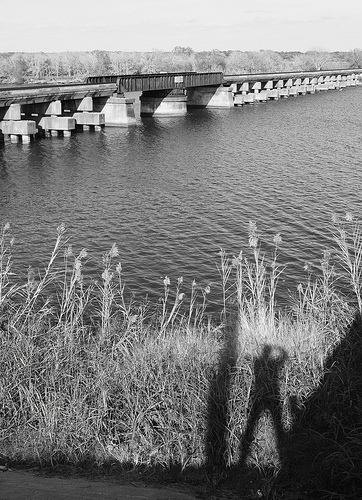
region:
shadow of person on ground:
[240, 332, 304, 458]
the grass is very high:
[4, 220, 348, 463]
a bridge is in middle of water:
[1, 45, 354, 124]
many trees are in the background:
[2, 43, 336, 108]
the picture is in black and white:
[0, 3, 353, 494]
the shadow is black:
[215, 333, 311, 491]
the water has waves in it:
[48, 141, 352, 322]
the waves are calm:
[29, 104, 359, 308]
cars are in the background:
[15, 73, 98, 97]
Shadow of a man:
[237, 337, 299, 473]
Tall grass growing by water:
[202, 219, 330, 329]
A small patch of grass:
[127, 360, 212, 433]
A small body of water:
[120, 183, 173, 229]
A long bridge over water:
[38, 47, 338, 111]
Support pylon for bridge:
[26, 97, 79, 132]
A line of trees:
[38, 39, 258, 65]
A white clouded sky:
[29, 5, 142, 43]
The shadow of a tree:
[198, 306, 238, 469]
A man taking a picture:
[241, 334, 302, 472]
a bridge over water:
[0, 42, 361, 131]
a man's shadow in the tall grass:
[238, 339, 292, 468]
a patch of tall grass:
[2, 221, 358, 480]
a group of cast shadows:
[197, 297, 361, 489]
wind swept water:
[17, 145, 358, 226]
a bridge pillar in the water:
[135, 91, 192, 120]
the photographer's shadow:
[238, 338, 296, 470]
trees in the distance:
[1, 49, 360, 77]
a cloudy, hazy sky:
[1, 1, 360, 51]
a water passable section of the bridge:
[89, 70, 231, 127]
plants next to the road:
[24, 324, 333, 434]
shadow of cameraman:
[235, 333, 285, 479]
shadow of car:
[132, 258, 358, 470]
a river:
[71, 106, 343, 257]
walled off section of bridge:
[112, 76, 225, 90]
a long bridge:
[6, 69, 356, 140]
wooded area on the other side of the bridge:
[1, 59, 335, 72]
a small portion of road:
[6, 479, 130, 498]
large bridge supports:
[5, 101, 97, 119]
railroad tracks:
[15, 78, 101, 97]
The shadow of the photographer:
[233, 339, 291, 466]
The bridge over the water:
[2, 66, 360, 148]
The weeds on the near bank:
[0, 207, 360, 496]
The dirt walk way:
[1, 466, 222, 499]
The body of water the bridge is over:
[1, 83, 361, 327]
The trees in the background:
[3, 44, 359, 91]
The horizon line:
[1, 44, 361, 55]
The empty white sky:
[0, 0, 360, 42]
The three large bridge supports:
[106, 83, 234, 127]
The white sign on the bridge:
[171, 74, 186, 87]